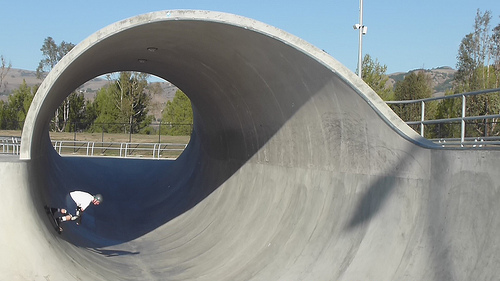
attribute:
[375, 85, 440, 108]
pole — metal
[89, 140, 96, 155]
pole — metal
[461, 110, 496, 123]
pole — metal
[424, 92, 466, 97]
pole — metal, silver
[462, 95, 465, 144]
fence pole — metal, silver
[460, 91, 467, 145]
pole — silver, metal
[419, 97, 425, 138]
pole — metal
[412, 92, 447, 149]
pole — metal, silver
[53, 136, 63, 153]
pole — metal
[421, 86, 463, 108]
pole — metal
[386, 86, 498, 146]
metal fence — surrounding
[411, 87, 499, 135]
fence pole — silver, metal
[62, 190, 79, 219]
shorts — black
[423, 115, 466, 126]
pole — silver, metal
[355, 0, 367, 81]
pole — gray 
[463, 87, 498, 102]
pole — metal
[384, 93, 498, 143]
fence — metal, silver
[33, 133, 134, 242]
person — skateboarding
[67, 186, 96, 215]
t-shirt — white, short sleeve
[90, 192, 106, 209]
head — person's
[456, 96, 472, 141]
fence pole — silver, metal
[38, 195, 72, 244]
shoes — black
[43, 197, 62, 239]
soles — black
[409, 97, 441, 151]
pole — silver, metal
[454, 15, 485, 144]
tree — tall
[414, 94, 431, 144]
pole — metal 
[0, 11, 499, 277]
ramp — skate, stone